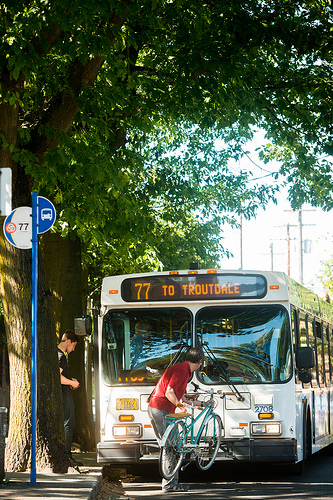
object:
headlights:
[249, 421, 282, 437]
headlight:
[112, 423, 142, 439]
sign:
[40, 206, 52, 221]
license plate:
[116, 398, 139, 411]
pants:
[147, 407, 180, 494]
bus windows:
[101, 304, 293, 389]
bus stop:
[0, 167, 59, 493]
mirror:
[74, 315, 92, 336]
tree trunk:
[0, 242, 79, 475]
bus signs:
[2, 192, 57, 251]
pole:
[30, 189, 40, 486]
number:
[134, 283, 151, 301]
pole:
[270, 243, 274, 271]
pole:
[287, 223, 290, 276]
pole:
[299, 203, 303, 285]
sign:
[134, 283, 244, 300]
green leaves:
[1, 1, 331, 291]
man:
[56, 327, 82, 468]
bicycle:
[158, 381, 224, 479]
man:
[147, 346, 206, 493]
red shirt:
[148, 361, 192, 413]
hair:
[186, 346, 205, 363]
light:
[213, 319, 233, 330]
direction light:
[119, 272, 267, 302]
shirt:
[57, 346, 72, 397]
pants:
[63, 394, 76, 460]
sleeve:
[169, 367, 186, 391]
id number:
[255, 405, 274, 413]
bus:
[72, 268, 332, 478]